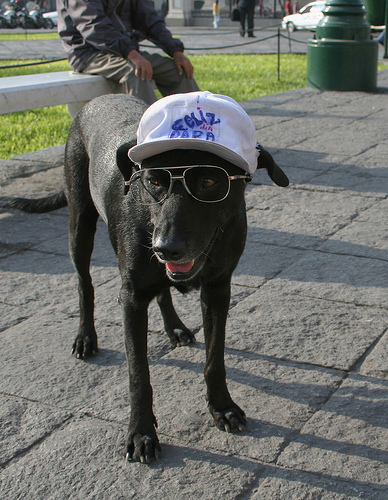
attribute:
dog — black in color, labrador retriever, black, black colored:
[64, 81, 288, 468]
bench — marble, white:
[4, 74, 133, 117]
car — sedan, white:
[278, 4, 329, 29]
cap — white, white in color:
[125, 88, 261, 170]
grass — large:
[5, 59, 387, 145]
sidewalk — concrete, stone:
[0, 66, 387, 500]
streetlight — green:
[304, 0, 379, 93]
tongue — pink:
[164, 258, 196, 276]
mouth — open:
[159, 234, 215, 283]